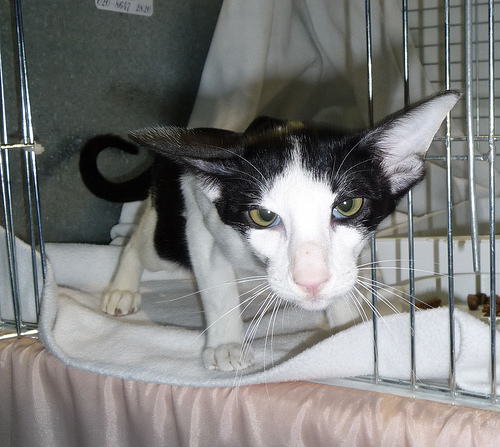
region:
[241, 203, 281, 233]
Eye of a cat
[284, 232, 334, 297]
Nose of a cat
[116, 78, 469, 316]
Head of a cat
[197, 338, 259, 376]
Paw of a cat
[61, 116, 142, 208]
Tail of a cat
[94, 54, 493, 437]
a cat in a cage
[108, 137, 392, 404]
a black and white cat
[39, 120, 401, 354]
a black and white cat in metal cage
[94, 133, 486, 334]
a cat on a blanket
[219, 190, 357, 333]
a cat iwth whiskers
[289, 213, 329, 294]
cat with nose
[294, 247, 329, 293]
the nose is pink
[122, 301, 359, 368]
the towel is white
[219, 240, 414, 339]
the whiskers are white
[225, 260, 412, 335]
whiskers on the face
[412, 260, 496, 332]
food in the dish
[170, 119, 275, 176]
the ear is black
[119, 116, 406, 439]
a black and white cat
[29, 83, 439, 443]
a cat in a cage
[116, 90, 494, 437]
a cat in a metal cage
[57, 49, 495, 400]
a cage with cat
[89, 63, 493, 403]
a metal cage iwth cat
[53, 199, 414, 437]
a cage iwth blanket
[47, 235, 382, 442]
cage with white balnekt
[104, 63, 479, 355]
a cat with ears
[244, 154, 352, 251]
a cat with eyes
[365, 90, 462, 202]
a cat's left ear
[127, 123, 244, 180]
a cat's right ear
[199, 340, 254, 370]
a cat's right paw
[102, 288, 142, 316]
a cat's right foot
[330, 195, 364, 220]
a cat's left eye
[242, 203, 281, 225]
a cat's right eye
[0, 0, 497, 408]
metal cage with cat in it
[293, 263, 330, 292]
a cat's pink nose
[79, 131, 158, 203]
a cat's black tail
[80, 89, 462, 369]
white and black cat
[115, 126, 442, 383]
a cat standing up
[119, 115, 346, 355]
a bnlack and whtie cat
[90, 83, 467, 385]
a black and white cat standin gup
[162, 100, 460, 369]
a cat in a cage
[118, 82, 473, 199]
long ears of cat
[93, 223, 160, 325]
back leg of cat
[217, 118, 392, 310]
face is white and black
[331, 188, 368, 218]
small right cat eye